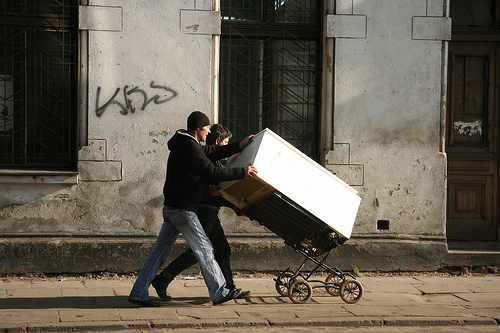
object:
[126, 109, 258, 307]
men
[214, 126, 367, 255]
appliance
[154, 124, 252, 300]
men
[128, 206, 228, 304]
jeans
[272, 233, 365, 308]
cart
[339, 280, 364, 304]
wheels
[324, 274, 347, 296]
wheels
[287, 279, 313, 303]
wheels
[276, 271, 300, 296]
wheels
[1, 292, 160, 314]
shadow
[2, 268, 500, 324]
sidewalk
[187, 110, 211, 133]
hat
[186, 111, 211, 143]
head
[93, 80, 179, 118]
paint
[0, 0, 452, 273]
wall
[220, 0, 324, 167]
bars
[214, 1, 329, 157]
window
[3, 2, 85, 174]
bars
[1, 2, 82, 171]
window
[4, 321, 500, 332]
curb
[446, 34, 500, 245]
door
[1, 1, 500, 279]
building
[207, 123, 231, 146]
hair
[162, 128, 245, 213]
coat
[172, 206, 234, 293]
pants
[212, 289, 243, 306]
shoes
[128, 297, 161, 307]
shoes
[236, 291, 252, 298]
shoes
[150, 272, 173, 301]
shoes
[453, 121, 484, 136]
paper